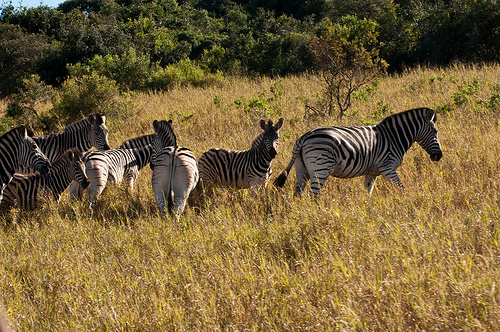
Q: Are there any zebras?
A: Yes, there is a zebra.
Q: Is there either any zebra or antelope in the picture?
A: Yes, there is a zebra.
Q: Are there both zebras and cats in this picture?
A: No, there is a zebra but no cats.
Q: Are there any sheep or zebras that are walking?
A: Yes, the zebra is walking.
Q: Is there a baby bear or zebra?
A: Yes, there is a baby zebra.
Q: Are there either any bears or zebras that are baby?
A: Yes, the zebra is a baby.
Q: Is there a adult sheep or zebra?
A: Yes, there is an adult zebra.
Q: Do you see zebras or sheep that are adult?
A: Yes, the zebra is adult.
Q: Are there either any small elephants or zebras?
A: Yes, there is a small zebra.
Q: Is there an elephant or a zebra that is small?
A: Yes, the zebra is small.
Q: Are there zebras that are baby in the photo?
A: Yes, there is a baby zebra.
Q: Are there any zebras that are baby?
A: Yes, there is a zebra that is a baby.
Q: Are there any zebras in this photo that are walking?
A: Yes, there is a zebra that is walking.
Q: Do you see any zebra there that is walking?
A: Yes, there is a zebra that is walking.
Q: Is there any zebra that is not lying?
A: Yes, there is a zebra that is walking.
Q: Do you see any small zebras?
A: Yes, there is a small zebra.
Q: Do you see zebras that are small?
A: Yes, there is a zebra that is small.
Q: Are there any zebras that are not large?
A: Yes, there is a small zebra.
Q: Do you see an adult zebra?
A: Yes, there is an adult zebra.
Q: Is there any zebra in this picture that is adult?
A: Yes, there is a zebra that is adult.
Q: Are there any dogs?
A: No, there are no dogs.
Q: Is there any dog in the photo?
A: No, there are no dogs.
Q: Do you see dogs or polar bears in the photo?
A: No, there are no dogs or polar bears.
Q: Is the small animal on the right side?
A: Yes, the zebra is on the right of the image.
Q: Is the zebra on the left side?
A: No, the zebra is on the right of the image.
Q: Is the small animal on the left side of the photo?
A: No, the zebra is on the right of the image.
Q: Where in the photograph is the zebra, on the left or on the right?
A: The zebra is on the right of the image.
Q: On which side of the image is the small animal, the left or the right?
A: The zebra is on the right of the image.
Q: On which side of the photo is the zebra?
A: The zebra is on the right of the image.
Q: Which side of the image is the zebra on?
A: The zebra is on the right of the image.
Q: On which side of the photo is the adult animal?
A: The zebra is on the right of the image.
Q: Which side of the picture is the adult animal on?
A: The zebra is on the right of the image.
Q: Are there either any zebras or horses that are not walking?
A: No, there is a zebra but it is walking.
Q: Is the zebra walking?
A: Yes, the zebra is walking.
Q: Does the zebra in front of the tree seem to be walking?
A: Yes, the zebra is walking.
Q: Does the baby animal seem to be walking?
A: Yes, the zebra is walking.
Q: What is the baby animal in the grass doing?
A: The zebra is walking.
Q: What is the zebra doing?
A: The zebra is walking.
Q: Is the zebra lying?
A: No, the zebra is walking.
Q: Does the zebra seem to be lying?
A: No, the zebra is walking.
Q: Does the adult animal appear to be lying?
A: No, the zebra is walking.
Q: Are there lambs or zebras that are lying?
A: No, there is a zebra but it is walking.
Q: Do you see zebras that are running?
A: No, there is a zebra but it is walking.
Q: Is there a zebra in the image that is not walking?
A: No, there is a zebra but it is walking.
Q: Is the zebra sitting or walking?
A: The zebra is walking.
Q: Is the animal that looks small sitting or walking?
A: The zebra is walking.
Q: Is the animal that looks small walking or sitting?
A: The zebra is walking.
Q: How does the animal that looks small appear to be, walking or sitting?
A: The zebra is walking.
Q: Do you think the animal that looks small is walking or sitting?
A: The zebra is walking.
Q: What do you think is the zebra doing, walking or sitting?
A: The zebra is walking.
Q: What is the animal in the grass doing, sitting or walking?
A: The zebra is walking.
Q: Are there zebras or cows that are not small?
A: No, there is a zebra but it is small.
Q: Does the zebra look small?
A: Yes, the zebra is small.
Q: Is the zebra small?
A: Yes, the zebra is small.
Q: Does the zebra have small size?
A: Yes, the zebra is small.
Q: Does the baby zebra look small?
A: Yes, the zebra is small.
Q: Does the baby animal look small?
A: Yes, the zebra is small.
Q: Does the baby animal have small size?
A: Yes, the zebra is small.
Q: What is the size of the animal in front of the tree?
A: The zebra is small.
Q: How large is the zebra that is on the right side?
A: The zebra is small.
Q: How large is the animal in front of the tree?
A: The zebra is small.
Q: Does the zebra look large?
A: No, the zebra is small.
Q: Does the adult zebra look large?
A: No, the zebra is small.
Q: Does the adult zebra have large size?
A: No, the zebra is small.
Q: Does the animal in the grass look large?
A: No, the zebra is small.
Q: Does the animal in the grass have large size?
A: No, the zebra is small.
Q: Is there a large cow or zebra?
A: No, there is a zebra but it is small.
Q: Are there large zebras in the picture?
A: No, there is a zebra but it is small.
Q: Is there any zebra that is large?
A: No, there is a zebra but it is small.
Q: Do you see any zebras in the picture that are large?
A: No, there is a zebra but it is small.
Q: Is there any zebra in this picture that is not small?
A: No, there is a zebra but it is small.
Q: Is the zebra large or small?
A: The zebra is small.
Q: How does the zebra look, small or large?
A: The zebra is small.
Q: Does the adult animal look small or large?
A: The zebra is small.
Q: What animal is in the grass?
A: The animal is a zebra.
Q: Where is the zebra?
A: The zebra is in the grass.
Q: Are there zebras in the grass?
A: Yes, there is a zebra in the grass.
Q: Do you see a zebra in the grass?
A: Yes, there is a zebra in the grass.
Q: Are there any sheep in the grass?
A: No, there is a zebra in the grass.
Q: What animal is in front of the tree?
A: The animal is a zebra.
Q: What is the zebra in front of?
A: The zebra is in front of the tree.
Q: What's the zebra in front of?
A: The zebra is in front of the tree.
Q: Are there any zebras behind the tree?
A: No, the zebra is in front of the tree.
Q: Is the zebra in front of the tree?
A: Yes, the zebra is in front of the tree.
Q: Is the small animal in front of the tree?
A: Yes, the zebra is in front of the tree.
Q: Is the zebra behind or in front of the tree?
A: The zebra is in front of the tree.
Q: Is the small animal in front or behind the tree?
A: The zebra is in front of the tree.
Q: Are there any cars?
A: No, there are no cars.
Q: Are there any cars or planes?
A: No, there are no cars or planes.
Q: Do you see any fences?
A: No, there are no fences.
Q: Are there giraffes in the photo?
A: No, there are no giraffes.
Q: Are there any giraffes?
A: No, there are no giraffes.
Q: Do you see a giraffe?
A: No, there are no giraffes.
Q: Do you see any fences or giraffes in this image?
A: No, there are no giraffes or fences.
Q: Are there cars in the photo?
A: No, there are no cars.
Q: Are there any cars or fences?
A: No, there are no cars or fences.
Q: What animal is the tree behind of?
A: The tree is behind the zebra.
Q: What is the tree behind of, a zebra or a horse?
A: The tree is behind a zebra.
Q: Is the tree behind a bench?
A: No, the tree is behind the zebra.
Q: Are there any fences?
A: No, there are no fences.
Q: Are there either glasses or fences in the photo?
A: No, there are no fences or glasses.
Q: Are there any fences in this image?
A: No, there are no fences.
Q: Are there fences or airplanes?
A: No, there are no fences or airplanes.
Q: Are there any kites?
A: No, there are no kites.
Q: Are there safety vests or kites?
A: No, there are no kites or safety vests.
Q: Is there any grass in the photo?
A: Yes, there is grass.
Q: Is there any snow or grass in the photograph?
A: Yes, there is grass.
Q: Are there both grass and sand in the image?
A: No, there is grass but no sand.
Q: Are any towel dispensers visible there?
A: No, there are no towel dispensers.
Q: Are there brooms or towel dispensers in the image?
A: No, there are no towel dispensers or brooms.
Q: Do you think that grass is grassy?
A: Yes, the grass is grassy.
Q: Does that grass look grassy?
A: Yes, the grass is grassy.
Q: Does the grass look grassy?
A: Yes, the grass is grassy.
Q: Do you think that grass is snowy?
A: No, the grass is grassy.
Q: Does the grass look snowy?
A: No, the grass is grassy.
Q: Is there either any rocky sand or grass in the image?
A: No, there is grass but it is grassy.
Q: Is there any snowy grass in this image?
A: No, there is grass but it is grassy.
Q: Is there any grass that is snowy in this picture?
A: No, there is grass but it is grassy.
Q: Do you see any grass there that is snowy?
A: No, there is grass but it is grassy.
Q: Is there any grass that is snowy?
A: No, there is grass but it is grassy.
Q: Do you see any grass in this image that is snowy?
A: No, there is grass but it is grassy.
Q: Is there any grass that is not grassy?
A: No, there is grass but it is grassy.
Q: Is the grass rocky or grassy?
A: The grass is grassy.